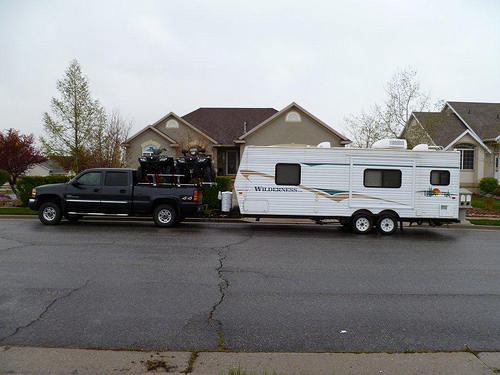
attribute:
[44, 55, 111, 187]
tree — large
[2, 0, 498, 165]
sky — blue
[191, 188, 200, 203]
light — red, rear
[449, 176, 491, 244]
mail box — tan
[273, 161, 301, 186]
window — square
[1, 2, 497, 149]
sky — overcast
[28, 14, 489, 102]
sky — blue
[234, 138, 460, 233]
rv — white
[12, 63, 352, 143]
cloud — white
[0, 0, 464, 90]
cloud — white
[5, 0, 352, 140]
cloud — white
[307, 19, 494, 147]
cloud — white